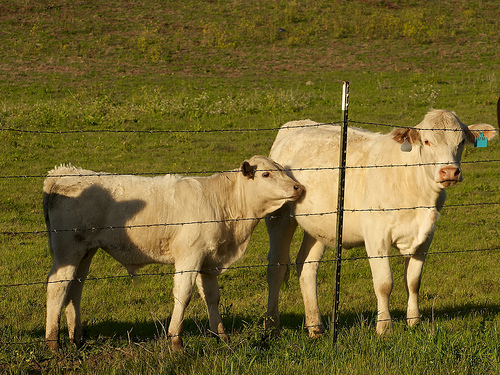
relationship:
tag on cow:
[475, 138, 489, 149] [265, 106, 496, 338]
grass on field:
[0, 0, 499, 374] [1, 0, 497, 372]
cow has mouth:
[40, 154, 302, 353] [436, 175, 463, 187]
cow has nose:
[40, 154, 302, 353] [437, 163, 464, 188]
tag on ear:
[471, 132, 493, 156] [463, 122, 495, 144]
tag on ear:
[475, 138, 489, 149] [461, 116, 499, 152]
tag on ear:
[475, 138, 489, 149] [378, 115, 430, 153]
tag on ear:
[475, 138, 489, 149] [465, 124, 495, 148]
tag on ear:
[399, 137, 413, 152] [390, 126, 411, 145]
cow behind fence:
[265, 106, 496, 338] [2, 78, 499, 340]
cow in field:
[40, 154, 302, 353] [1, 0, 497, 372]